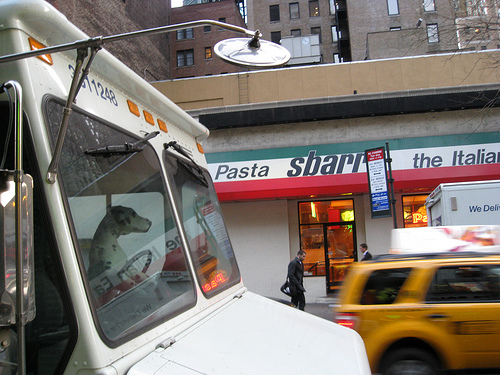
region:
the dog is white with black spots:
[90, 201, 159, 291]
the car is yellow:
[346, 261, 434, 342]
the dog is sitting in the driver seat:
[87, 197, 161, 259]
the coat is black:
[285, 259, 316, 301]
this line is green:
[248, 142, 288, 162]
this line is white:
[220, 160, 280, 184]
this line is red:
[226, 179, 276, 198]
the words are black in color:
[411, 147, 491, 171]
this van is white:
[230, 338, 299, 370]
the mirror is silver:
[6, 155, 42, 315]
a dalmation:
[85, 198, 160, 312]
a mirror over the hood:
[203, 24, 308, 84]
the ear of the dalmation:
[105, 199, 131, 227]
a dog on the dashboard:
[83, 189, 177, 314]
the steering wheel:
[126, 237, 166, 276]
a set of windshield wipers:
[90, 107, 213, 186]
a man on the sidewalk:
[272, 239, 317, 314]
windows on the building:
[171, 18, 214, 77]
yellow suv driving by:
[319, 251, 499, 353]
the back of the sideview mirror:
[0, 164, 38, 326]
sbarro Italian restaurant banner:
[219, 133, 489, 274]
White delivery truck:
[36, 13, 346, 370]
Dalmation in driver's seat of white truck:
[71, 189, 173, 309]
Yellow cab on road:
[334, 254, 494, 368]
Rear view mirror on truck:
[62, 4, 289, 94]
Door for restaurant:
[298, 202, 357, 302]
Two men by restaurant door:
[288, 233, 380, 300]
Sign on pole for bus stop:
[355, 137, 393, 232]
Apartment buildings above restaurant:
[54, 2, 489, 61]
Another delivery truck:
[415, 173, 497, 220]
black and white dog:
[66, 193, 157, 311]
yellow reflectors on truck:
[117, 89, 173, 136]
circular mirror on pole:
[197, 13, 292, 73]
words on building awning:
[242, 140, 402, 197]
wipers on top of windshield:
[84, 120, 217, 208]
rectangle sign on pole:
[363, 140, 398, 223]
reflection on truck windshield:
[112, 224, 217, 315]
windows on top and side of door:
[290, 193, 365, 303]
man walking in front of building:
[277, 242, 316, 311]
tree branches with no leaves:
[417, 10, 494, 71]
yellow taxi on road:
[316, 253, 494, 357]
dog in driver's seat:
[86, 197, 158, 285]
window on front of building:
[426, 21, 439, 42]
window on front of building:
[386, 0, 397, 17]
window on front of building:
[288, 0, 301, 22]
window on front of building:
[174, 47, 193, 65]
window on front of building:
[308, 0, 323, 19]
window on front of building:
[203, 46, 212, 63]